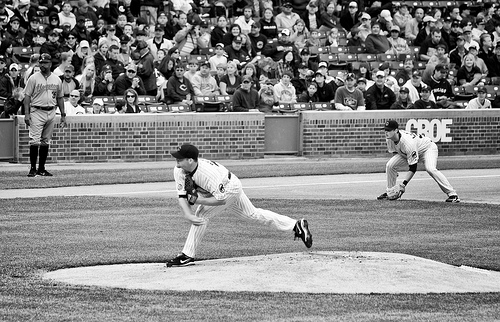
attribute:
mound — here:
[217, 228, 356, 288]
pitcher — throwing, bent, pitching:
[135, 135, 268, 228]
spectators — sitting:
[106, 30, 385, 144]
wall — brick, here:
[92, 105, 198, 174]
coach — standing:
[26, 43, 93, 155]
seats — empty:
[313, 54, 427, 90]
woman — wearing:
[118, 92, 156, 111]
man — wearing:
[338, 71, 369, 103]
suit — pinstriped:
[191, 165, 255, 223]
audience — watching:
[102, 29, 387, 121]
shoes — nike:
[289, 206, 316, 249]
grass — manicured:
[55, 191, 141, 237]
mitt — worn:
[385, 186, 433, 201]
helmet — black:
[34, 56, 59, 60]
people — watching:
[103, 15, 228, 95]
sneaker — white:
[280, 207, 368, 283]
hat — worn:
[165, 140, 210, 162]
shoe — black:
[153, 247, 238, 282]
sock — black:
[16, 146, 48, 166]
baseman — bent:
[361, 110, 481, 196]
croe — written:
[391, 102, 500, 159]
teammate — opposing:
[21, 31, 98, 126]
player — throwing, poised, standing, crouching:
[167, 146, 311, 268]